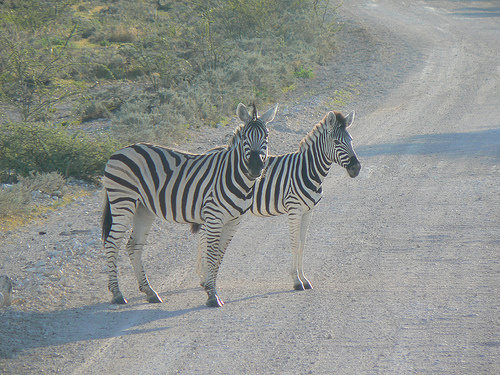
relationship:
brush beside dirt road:
[0, 1, 349, 234] [0, 0, 499, 374]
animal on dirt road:
[100, 102, 283, 308] [0, 0, 499, 374]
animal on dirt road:
[96, 101, 283, 309] [0, 0, 499, 374]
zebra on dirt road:
[195, 106, 358, 297] [0, 0, 499, 374]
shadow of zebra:
[1, 292, 156, 360] [93, 100, 285, 323]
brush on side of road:
[1, 2, 333, 209] [126, 7, 495, 370]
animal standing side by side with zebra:
[96, 101, 283, 309] [219, 107, 368, 290]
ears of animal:
[233, 96, 284, 124] [99, 104, 277, 324]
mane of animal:
[295, 107, 345, 158] [241, 114, 371, 304]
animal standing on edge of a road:
[96, 101, 283, 309] [126, 7, 495, 370]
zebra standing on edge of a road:
[187, 106, 362, 292] [126, 7, 495, 370]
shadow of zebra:
[0, 284, 294, 360] [89, 109, 276, 304]